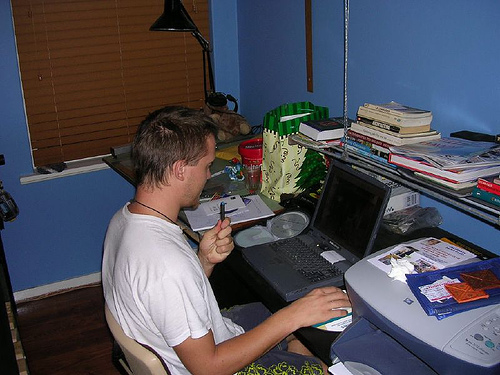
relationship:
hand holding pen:
[198, 216, 234, 266] [217, 199, 228, 222]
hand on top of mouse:
[293, 286, 350, 327] [329, 287, 353, 315]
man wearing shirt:
[101, 104, 352, 374] [100, 198, 245, 374]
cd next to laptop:
[270, 212, 305, 240] [241, 158, 391, 302]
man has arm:
[101, 104, 352, 374] [151, 255, 296, 374]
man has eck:
[101, 104, 352, 374] [125, 185, 181, 224]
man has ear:
[101, 104, 352, 374] [172, 155, 188, 182]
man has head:
[101, 104, 352, 374] [131, 101, 218, 209]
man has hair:
[101, 104, 352, 374] [131, 105, 216, 193]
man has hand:
[101, 104, 352, 374] [198, 216, 234, 266]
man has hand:
[101, 104, 352, 374] [293, 286, 350, 327]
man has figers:
[101, 104, 352, 374] [215, 215, 231, 255]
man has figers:
[101, 104, 352, 374] [312, 282, 351, 320]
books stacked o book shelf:
[298, 96, 499, 207] [290, 135, 498, 235]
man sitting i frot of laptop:
[101, 104, 352, 374] [241, 158, 391, 302]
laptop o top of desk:
[241, 158, 391, 302] [103, 128, 498, 367]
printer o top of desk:
[328, 234, 498, 373] [103, 128, 498, 367]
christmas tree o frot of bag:
[293, 142, 326, 197] [259, 101, 329, 204]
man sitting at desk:
[101, 104, 352, 374] [103, 128, 498, 367]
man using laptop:
[101, 104, 352, 374] [241, 158, 391, 302]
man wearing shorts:
[101, 104, 352, 374] [217, 302, 325, 374]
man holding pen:
[101, 104, 352, 374] [217, 199, 228, 222]